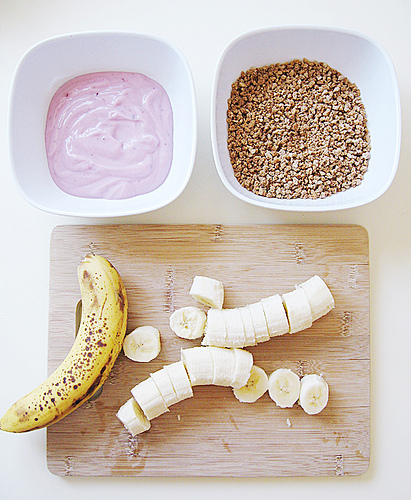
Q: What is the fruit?
A: Banana.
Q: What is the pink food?
A: Yogurt.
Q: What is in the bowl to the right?
A: Nuts.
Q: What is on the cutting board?
A: Chopped bananas.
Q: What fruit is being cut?
A: A banana.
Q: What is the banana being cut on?
A: A cutting board.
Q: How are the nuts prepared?
A: Chopped.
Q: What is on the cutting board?
A: A peeled banana.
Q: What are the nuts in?
A: A white bowl.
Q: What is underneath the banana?
A: A wooden cutting board.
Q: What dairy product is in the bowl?
A: Yogurt.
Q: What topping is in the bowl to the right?
A: Granola.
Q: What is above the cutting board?
A: Two bowls.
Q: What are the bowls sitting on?
A: A white surface.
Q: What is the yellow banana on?
A: A cutting board.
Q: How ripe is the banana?
A: Over ripe.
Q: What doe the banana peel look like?
A: Yellow with brown spots.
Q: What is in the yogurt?
A: Pink specks.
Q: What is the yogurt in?
A: A bowl.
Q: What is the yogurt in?
A: A dish.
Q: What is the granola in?
A: A bowl.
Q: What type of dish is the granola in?
A: A bowl.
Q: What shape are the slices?
A: Round.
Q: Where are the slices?
A: On the cutting board.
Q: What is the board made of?
A: Wood.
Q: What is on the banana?
A: Spots.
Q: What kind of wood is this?
A: Bamboo.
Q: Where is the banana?
A: On the cutting board.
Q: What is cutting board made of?
A: Wood.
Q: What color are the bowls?
A: White.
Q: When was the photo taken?
A: Daytime.